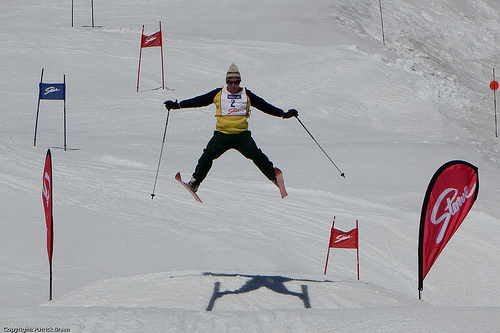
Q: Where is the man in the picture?
A: In the air.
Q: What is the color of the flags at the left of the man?
A: Red.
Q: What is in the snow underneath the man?
A: Shadow.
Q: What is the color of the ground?
A: White.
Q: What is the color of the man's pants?
A: Black.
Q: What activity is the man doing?
A: Skiing.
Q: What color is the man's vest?
A: Yellow.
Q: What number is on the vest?
A: 2.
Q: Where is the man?
A: In the air.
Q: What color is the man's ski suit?
A: Black.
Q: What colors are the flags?
A: Red and Blue.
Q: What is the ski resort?
A: Stowe.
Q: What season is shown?
A: Winter.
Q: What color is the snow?
A: White.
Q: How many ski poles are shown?
A: 2.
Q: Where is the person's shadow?
A: On the snow.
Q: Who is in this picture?
A: A skier.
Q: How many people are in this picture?
A: One.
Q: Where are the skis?
A: On the person's feet.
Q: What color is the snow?
A: White.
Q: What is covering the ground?
A: Snow.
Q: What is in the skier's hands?
A: Poles.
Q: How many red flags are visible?
A: Four.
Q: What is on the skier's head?
A: Hat.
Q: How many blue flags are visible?
A: One.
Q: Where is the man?
A: In the air.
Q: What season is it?
A: Winter.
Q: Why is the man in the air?
A: He jumped.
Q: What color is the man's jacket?
A: Yellow.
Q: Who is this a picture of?
A: A skier.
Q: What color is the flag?
A: Red.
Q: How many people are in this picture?
A: One.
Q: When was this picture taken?
A: During the day.